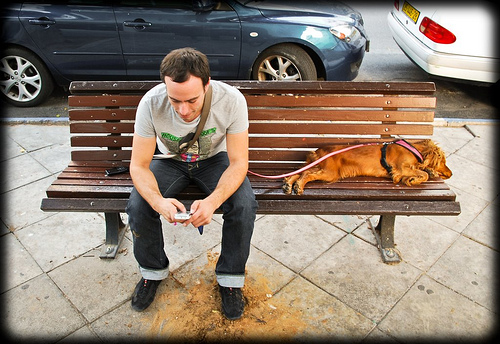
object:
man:
[120, 46, 262, 321]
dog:
[280, 135, 456, 197]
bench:
[37, 77, 461, 263]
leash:
[248, 136, 424, 180]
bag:
[152, 81, 215, 160]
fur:
[317, 138, 379, 178]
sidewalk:
[1, 119, 498, 340]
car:
[0, 0, 373, 110]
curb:
[1, 113, 497, 130]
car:
[381, 0, 500, 82]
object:
[173, 211, 193, 222]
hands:
[153, 196, 189, 227]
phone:
[104, 164, 130, 178]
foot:
[214, 278, 248, 321]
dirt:
[136, 251, 306, 343]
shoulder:
[213, 81, 249, 126]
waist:
[156, 146, 227, 161]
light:
[417, 15, 457, 45]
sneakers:
[215, 283, 247, 322]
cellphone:
[171, 210, 193, 221]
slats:
[67, 78, 437, 93]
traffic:
[2, 0, 498, 116]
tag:
[396, 1, 423, 26]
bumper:
[386, 12, 497, 85]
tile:
[429, 234, 497, 344]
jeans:
[123, 151, 261, 290]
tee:
[129, 80, 250, 167]